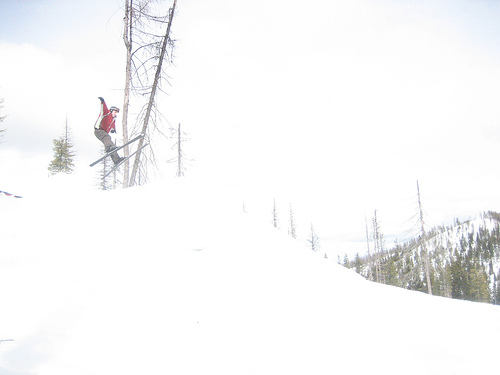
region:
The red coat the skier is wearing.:
[95, 109, 115, 130]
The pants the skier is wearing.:
[100, 130, 124, 165]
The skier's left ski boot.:
[105, 141, 120, 152]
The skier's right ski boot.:
[113, 155, 125, 165]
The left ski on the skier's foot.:
[80, 133, 152, 164]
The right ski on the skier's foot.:
[101, 139, 158, 177]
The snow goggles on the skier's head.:
[111, 104, 122, 113]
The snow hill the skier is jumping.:
[7, 165, 354, 374]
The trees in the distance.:
[255, 175, 485, 241]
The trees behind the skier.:
[38, 81, 118, 193]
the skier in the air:
[81, 88, 152, 184]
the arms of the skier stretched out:
[90, 92, 121, 136]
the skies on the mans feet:
[90, 128, 150, 181]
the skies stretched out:
[91, 126, 150, 193]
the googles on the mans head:
[110, 106, 120, 116]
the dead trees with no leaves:
[116, 0, 175, 97]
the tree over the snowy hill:
[44, 128, 78, 178]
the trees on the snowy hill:
[435, 211, 497, 278]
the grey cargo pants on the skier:
[95, 126, 123, 166]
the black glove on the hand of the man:
[98, 93, 105, 104]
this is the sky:
[335, 27, 450, 134]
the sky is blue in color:
[11, 3, 60, 28]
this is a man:
[84, 89, 142, 169]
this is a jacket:
[99, 111, 116, 128]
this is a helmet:
[108, 102, 121, 110]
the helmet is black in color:
[109, 106, 123, 113]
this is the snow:
[191, 259, 305, 368]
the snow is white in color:
[189, 225, 291, 328]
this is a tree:
[464, 260, 498, 305]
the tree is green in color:
[467, 272, 485, 288]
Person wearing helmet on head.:
[110, 101, 129, 117]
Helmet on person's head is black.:
[108, 100, 140, 132]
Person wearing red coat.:
[85, 105, 122, 126]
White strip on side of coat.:
[89, 105, 118, 130]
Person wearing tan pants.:
[88, 127, 130, 160]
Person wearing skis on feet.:
[85, 108, 146, 200]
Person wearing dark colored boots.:
[106, 139, 131, 174]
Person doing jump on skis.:
[83, 130, 167, 221]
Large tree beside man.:
[100, 25, 166, 239]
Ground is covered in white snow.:
[213, 228, 325, 340]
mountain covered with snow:
[94, 180, 361, 353]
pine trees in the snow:
[376, 228, 498, 312]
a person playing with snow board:
[86, 94, 146, 187]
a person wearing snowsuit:
[97, 95, 130, 160]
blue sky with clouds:
[269, 10, 498, 135]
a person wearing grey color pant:
[96, 127, 130, 172]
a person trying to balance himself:
[95, 95, 122, 161]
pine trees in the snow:
[50, 120, 71, 192]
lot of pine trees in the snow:
[384, 223, 489, 306]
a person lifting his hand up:
[97, 93, 113, 124]